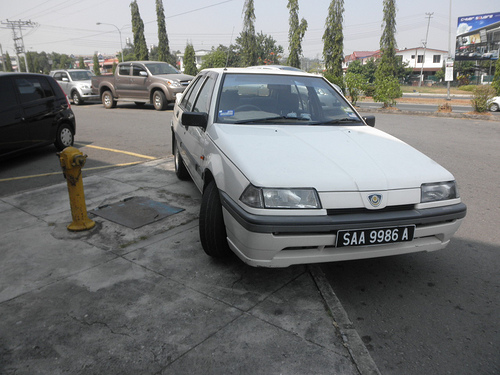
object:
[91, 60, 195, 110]
truck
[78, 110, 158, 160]
street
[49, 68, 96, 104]
car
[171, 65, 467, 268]
car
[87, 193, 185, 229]
curb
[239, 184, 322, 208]
headlight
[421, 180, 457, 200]
headlight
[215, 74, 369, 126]
windshield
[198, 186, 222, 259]
front wheel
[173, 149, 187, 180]
rear wheel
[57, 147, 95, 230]
hydrant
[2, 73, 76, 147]
van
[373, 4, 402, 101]
tree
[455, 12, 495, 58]
sign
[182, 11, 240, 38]
sky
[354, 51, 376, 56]
roof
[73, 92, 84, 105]
front wheel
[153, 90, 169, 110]
tire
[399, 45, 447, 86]
house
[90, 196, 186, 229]
grate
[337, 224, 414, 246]
license plate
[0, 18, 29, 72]
power pole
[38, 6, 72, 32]
wire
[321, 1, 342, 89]
tree